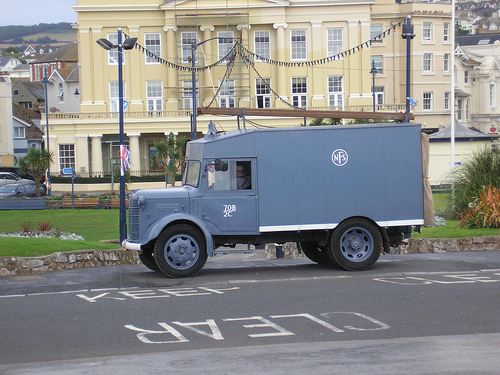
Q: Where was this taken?
A: Outside on the street.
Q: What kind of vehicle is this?
A: Truck.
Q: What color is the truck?
A: Blue.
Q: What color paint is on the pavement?
A: White.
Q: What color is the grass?
A: Green.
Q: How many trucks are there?
A: One.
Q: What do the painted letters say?
A: KEEP CLEAR.